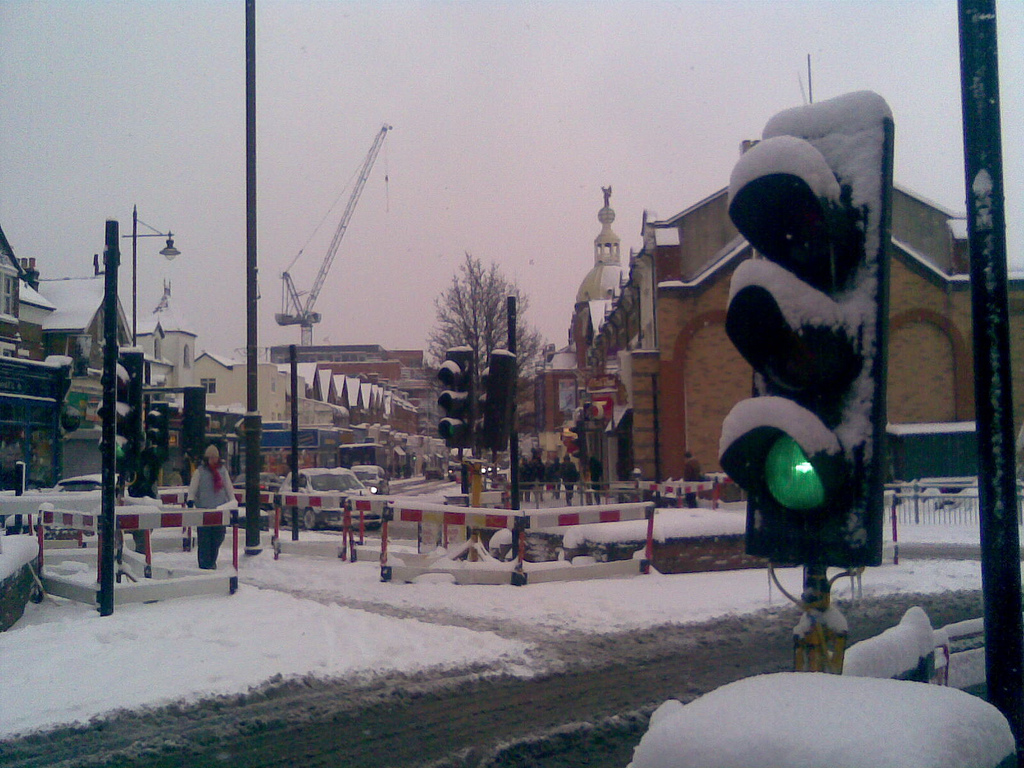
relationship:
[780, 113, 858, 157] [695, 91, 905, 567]
snow covered light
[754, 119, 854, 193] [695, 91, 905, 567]
snow covered light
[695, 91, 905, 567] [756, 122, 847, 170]
light covered snow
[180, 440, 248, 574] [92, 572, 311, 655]
person in snow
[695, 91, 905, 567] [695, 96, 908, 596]
light on traffic signal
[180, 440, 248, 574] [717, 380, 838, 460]
person walking on snow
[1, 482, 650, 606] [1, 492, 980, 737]
barriers around sidewalk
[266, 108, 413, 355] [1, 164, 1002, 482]
crane behind buildings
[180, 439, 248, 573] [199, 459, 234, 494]
person wearing scarf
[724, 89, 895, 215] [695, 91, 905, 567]
snow covering light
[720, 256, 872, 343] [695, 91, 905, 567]
snow covering light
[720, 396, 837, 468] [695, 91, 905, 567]
snow covering light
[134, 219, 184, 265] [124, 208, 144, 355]
lamp on a post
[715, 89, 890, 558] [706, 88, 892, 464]
light covered in snow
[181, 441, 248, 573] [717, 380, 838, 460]
woman walking in snow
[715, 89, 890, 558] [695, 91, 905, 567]
light on light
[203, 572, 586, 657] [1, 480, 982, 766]
pathway in snow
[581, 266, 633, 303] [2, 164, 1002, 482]
dome on top of buildings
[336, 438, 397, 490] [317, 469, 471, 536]
bus driving down road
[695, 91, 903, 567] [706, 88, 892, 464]
light covered in snow